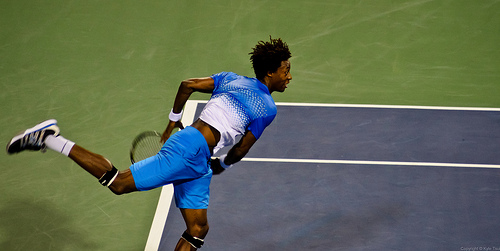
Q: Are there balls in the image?
A: No, there are no balls.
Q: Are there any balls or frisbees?
A: No, there are no balls or frisbees.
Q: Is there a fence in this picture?
A: No, there are no fences.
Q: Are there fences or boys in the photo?
A: No, there are no fences or boys.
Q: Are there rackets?
A: Yes, there is a racket.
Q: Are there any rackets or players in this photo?
A: Yes, there is a racket.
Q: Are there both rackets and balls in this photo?
A: No, there is a racket but no balls.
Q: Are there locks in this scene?
A: No, there are no locks.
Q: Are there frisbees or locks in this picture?
A: No, there are no locks or frisbees.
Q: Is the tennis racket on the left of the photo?
A: Yes, the tennis racket is on the left of the image.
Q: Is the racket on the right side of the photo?
A: No, the racket is on the left of the image.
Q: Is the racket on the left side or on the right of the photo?
A: The racket is on the left of the image.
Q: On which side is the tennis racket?
A: The tennis racket is on the left of the image.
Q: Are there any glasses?
A: No, there are no glasses.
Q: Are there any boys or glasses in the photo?
A: No, there are no glasses or boys.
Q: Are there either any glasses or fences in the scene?
A: No, there are no glasses or fences.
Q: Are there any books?
A: No, there are no books.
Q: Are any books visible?
A: No, there are no books.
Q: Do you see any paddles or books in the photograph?
A: No, there are no books or paddles.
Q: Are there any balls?
A: No, there are no balls.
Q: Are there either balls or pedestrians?
A: No, there are no balls or pedestrians.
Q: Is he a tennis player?
A: Yes, this is a tennis player.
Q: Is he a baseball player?
A: No, this is a tennis player.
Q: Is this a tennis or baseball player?
A: This is a tennis player.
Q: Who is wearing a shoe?
A: The player is wearing a shoe.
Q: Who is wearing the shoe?
A: The player is wearing a shoe.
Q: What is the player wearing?
A: The player is wearing a shoe.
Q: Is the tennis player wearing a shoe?
A: Yes, the player is wearing a shoe.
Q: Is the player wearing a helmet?
A: No, the player is wearing a shoe.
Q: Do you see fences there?
A: No, there are no fences.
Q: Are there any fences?
A: No, there are no fences.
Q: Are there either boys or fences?
A: No, there are no fences or boys.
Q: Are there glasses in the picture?
A: No, there are no glasses.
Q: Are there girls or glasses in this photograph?
A: No, there are no glasses or girls.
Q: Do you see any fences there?
A: No, there are no fences.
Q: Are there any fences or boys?
A: No, there are no fences or boys.